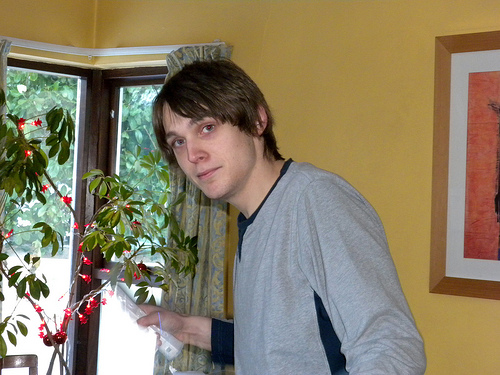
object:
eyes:
[197, 122, 217, 136]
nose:
[185, 147, 208, 162]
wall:
[271, 83, 296, 142]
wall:
[358, 145, 418, 166]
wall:
[292, 117, 368, 142]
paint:
[313, 100, 329, 120]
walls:
[302, 147, 331, 166]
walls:
[331, 123, 385, 134]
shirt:
[207, 159, 429, 374]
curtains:
[165, 43, 225, 370]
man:
[135, 57, 427, 374]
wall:
[399, 0, 481, 13]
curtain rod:
[1, 33, 224, 69]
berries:
[53, 332, 69, 345]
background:
[1, 0, 500, 374]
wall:
[0, 0, 98, 54]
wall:
[95, 2, 170, 34]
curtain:
[155, 38, 232, 374]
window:
[0, 58, 222, 374]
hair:
[150, 56, 284, 165]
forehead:
[155, 100, 206, 129]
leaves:
[133, 283, 164, 308]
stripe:
[158, 312, 163, 328]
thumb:
[135, 310, 162, 326]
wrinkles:
[341, 307, 431, 374]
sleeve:
[299, 179, 425, 374]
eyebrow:
[161, 130, 179, 142]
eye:
[168, 135, 186, 149]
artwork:
[427, 27, 499, 307]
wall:
[452, 353, 498, 374]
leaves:
[43, 104, 77, 164]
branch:
[16, 110, 47, 141]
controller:
[109, 285, 186, 365]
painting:
[462, 69, 499, 265]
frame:
[429, 30, 499, 301]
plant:
[0, 107, 199, 374]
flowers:
[76, 271, 91, 284]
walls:
[400, 273, 434, 296]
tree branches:
[0, 104, 199, 310]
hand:
[136, 304, 197, 348]